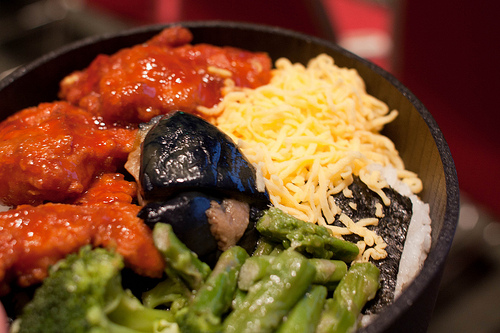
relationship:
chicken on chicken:
[57, 25, 270, 124] [61, 28, 288, 115]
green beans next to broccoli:
[180, 235, 378, 333] [22, 244, 161, 331]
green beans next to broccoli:
[286, 219, 356, 252] [22, 244, 161, 331]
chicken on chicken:
[57, 25, 270, 124] [5, 23, 268, 275]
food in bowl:
[0, 23, 430, 333] [0, 20, 460, 333]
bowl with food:
[0, 20, 460, 333] [0, 23, 430, 333]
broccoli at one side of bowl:
[16, 244, 171, 333] [0, 20, 461, 331]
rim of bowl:
[209, 25, 464, 325] [0, 20, 461, 331]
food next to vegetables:
[0, 30, 269, 310] [21, 203, 385, 326]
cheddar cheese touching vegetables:
[199, 54, 424, 265] [238, 237, 347, 309]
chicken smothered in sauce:
[0, 12, 245, 302] [2, 23, 277, 302]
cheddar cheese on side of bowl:
[199, 54, 424, 265] [0, 20, 460, 333]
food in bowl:
[17, 37, 394, 330] [0, 20, 460, 333]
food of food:
[137, 111, 267, 265] [0, 23, 430, 333]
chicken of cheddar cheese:
[0, 100, 161, 290] [199, 54, 424, 265]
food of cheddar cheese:
[137, 111, 267, 251] [199, 54, 424, 265]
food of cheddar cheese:
[0, 23, 430, 333] [199, 54, 424, 265]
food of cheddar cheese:
[9, 248, 176, 331] [199, 54, 424, 265]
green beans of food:
[180, 235, 378, 333] [0, 23, 430, 333]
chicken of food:
[57, 25, 270, 124] [20, 62, 321, 282]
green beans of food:
[180, 235, 378, 333] [229, 222, 391, 305]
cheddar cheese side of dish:
[199, 54, 424, 265] [16, 35, 440, 332]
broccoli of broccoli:
[16, 244, 171, 333] [28, 203, 396, 331]